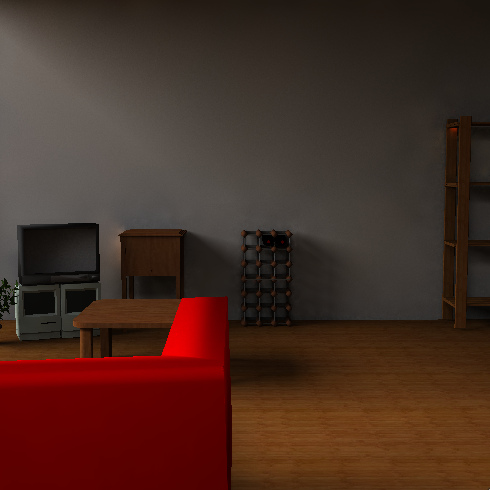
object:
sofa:
[0, 295, 233, 489]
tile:
[0, 319, 490, 489]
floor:
[0, 319, 489, 489]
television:
[16, 222, 101, 288]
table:
[71, 298, 184, 360]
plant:
[0, 276, 23, 328]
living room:
[0, 0, 487, 489]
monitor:
[15, 283, 61, 342]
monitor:
[59, 285, 101, 336]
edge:
[440, 113, 469, 331]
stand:
[439, 114, 490, 332]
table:
[117, 228, 190, 298]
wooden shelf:
[440, 112, 489, 330]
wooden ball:
[239, 230, 245, 238]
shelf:
[239, 228, 293, 252]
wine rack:
[238, 228, 295, 327]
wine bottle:
[260, 231, 275, 254]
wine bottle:
[273, 234, 290, 252]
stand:
[15, 283, 100, 342]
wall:
[0, 0, 489, 323]